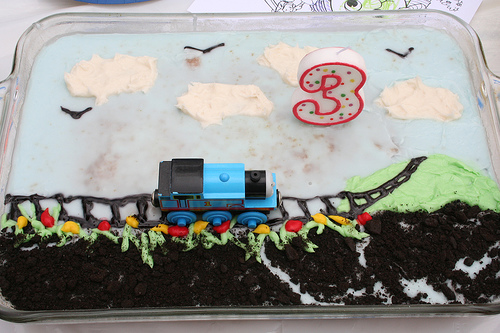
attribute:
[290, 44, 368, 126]
candle — white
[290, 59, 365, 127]
outline — red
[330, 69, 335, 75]
dot — colored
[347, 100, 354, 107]
dot — colored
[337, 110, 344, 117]
dot — colored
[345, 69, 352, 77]
dot — colored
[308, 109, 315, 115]
dot — colored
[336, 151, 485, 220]
icing — green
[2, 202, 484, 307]
cake — crumbled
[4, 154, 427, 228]
icing — black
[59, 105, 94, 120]
icing — black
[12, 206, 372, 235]
icing — red, yellow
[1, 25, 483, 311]
cake — rectangular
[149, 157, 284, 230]
train — blue, black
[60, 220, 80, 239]
icing — yellow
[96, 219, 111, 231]
icing — orange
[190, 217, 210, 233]
icing — yellow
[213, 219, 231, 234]
icing — orange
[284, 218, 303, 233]
icing — orange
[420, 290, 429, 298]
oreo — crushed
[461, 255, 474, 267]
oreo — crushed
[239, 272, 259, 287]
oreo — crushed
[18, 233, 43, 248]
oreo — crushed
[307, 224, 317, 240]
oreo — crushed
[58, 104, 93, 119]
bird — black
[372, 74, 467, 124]
cloud — white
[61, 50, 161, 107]
cloud — white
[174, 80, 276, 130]
cloud — white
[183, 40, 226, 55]
bird — black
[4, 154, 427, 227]
track — black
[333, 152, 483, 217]
mountain — green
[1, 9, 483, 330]
dish — glass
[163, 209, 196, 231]
wheel — blue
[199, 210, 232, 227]
wheel — blue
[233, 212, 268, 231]
wheel — blue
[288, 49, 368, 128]
candle — number 3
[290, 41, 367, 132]
candle — red, white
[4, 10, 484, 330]
cake pan — glass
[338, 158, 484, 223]
frosting — green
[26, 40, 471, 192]
frosting — blue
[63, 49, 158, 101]
frosting — white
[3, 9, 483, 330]
pan — rectangular